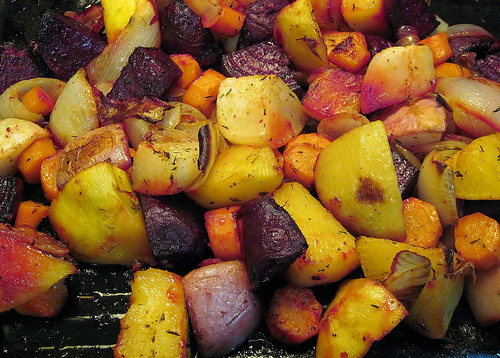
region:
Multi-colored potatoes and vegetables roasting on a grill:
[5, 0, 497, 352]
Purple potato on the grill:
[247, 195, 303, 287]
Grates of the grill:
[22, 273, 137, 351]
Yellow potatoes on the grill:
[276, 117, 401, 288]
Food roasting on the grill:
[0, 3, 494, 350]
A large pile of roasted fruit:
[2, 2, 495, 357]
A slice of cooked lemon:
[318, 120, 403, 236]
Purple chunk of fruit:
[235, 197, 305, 293]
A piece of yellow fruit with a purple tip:
[365, 42, 433, 109]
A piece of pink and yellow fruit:
[3, 234, 76, 307]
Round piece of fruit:
[456, 210, 498, 265]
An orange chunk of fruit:
[171, 69, 224, 109]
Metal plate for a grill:
[60, 280, 118, 356]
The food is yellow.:
[116, 270, 191, 354]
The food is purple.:
[237, 196, 309, 298]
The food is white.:
[218, 77, 303, 147]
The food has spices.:
[107, 269, 196, 357]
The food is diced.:
[227, 199, 308, 289]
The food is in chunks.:
[233, 197, 308, 296]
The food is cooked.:
[311, 125, 408, 251]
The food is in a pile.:
[14, 10, 493, 342]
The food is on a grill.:
[22, 257, 137, 354]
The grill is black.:
[16, 260, 134, 352]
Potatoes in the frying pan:
[11, 8, 450, 356]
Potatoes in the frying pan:
[33, 179, 243, 322]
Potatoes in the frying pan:
[18, 53, 157, 349]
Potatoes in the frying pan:
[2, 4, 239, 143]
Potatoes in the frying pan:
[273, 0, 484, 122]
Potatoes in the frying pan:
[125, 235, 387, 335]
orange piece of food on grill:
[314, 275, 409, 356]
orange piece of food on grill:
[271, 180, 358, 283]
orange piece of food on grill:
[353, 230, 448, 290]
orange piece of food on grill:
[401, 195, 441, 242]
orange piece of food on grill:
[452, 213, 499, 272]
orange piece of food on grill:
[45, 164, 157, 265]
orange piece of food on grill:
[108, 267, 193, 355]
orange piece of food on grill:
[1, 231, 76, 309]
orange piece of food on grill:
[16, 135, 57, 187]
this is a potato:
[215, 77, 297, 144]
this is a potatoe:
[62, 181, 145, 261]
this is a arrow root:
[240, 202, 315, 282]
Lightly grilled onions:
[2, 4, 153, 109]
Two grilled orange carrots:
[169, 48, 226, 112]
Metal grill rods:
[7, 272, 130, 357]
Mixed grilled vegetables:
[0, 77, 140, 277]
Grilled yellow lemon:
[314, 119, 402, 237]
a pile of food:
[19, 11, 496, 356]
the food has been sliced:
[20, 16, 495, 349]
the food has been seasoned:
[18, 6, 498, 355]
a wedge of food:
[311, 116, 412, 238]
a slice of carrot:
[194, 195, 246, 263]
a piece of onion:
[182, 255, 269, 354]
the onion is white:
[79, 13, 164, 96]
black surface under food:
[39, 277, 125, 354]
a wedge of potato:
[201, 57, 305, 146]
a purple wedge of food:
[226, 186, 320, 293]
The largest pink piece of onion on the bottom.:
[183, 261, 262, 357]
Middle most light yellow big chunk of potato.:
[216, 74, 309, 149]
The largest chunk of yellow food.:
[314, 119, 406, 240]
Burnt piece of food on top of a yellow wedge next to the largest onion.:
[238, 191, 308, 288]